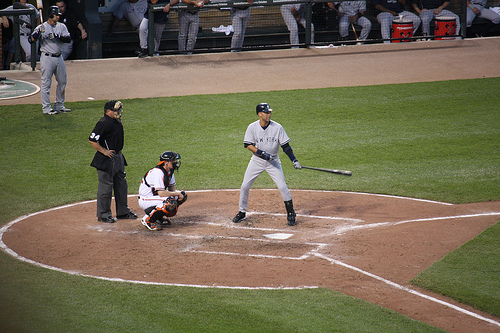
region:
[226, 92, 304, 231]
Man wearing a gray uniform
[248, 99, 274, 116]
Helmet on man's head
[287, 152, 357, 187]
Bat in man's hand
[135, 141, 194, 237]
Man crouching in dirt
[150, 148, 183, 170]
Helmet on man's head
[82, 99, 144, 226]
Man wearing a black shirt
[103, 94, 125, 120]
Mask on man's face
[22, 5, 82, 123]
Man wearing a gray uniform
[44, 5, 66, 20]
Helmet on man's head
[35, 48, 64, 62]
Belt around man's waist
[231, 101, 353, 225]
New York Yankees baseball player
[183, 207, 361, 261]
Home plate and the batter's box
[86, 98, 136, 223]
Baseball umpire dressed all in black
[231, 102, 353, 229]
Baseball player with a bat preparing to hit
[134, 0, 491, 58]
Baseball players sitting and standing in a dugout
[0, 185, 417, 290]
White chalk lines on a baseball field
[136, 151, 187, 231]
Baseball catcher preparing to catch a pitch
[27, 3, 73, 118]
Baseball player next to the on deck circle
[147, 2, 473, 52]
Black wire fence along the dugout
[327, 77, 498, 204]
Short green grass on a baseball field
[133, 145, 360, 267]
catcher is behind the home base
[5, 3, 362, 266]
people playing baseball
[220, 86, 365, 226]
player holding a bat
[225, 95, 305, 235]
player has a blue helmet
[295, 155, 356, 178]
a large bat of baseball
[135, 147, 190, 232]
the catcher is crouched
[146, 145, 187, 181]
catcher wears a helmet with face protection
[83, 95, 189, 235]
the umpire stands behind the catcher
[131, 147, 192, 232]
the catcher wears shin protections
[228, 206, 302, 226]
a pair of black shoes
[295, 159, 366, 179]
long black and silver bat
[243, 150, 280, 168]
crease in player's pants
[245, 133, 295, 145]
black words on gray shirt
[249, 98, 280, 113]
black helmet on player's head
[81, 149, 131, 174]
black bag at side of umpire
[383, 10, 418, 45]
red cooler in the dugout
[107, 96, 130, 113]
white face mask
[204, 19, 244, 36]
white towel in the dugout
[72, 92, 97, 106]
white spot on the field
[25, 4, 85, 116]
player standing on the field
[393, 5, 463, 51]
two dustbins kept in the ground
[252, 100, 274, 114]
a person wearing hat on his head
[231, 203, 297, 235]
a person wearing black color shoes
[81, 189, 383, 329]
a ground marked with white color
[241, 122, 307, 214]
a person wearing sports dress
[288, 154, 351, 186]
a person holding baseball bat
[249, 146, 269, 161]
a person wearing gloves on his hand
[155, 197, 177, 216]
a person wearing knee pad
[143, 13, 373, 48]
people sitting in the stadium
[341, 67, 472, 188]
dirt with green grass